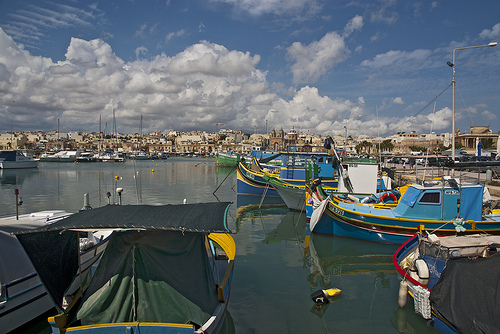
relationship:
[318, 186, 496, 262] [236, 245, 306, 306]
boat in water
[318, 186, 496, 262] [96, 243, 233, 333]
boat with tarp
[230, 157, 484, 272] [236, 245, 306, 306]
boats in water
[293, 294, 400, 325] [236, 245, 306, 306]
object in water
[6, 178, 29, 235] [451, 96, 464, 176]
light on a pole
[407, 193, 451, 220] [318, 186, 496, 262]
cabin of boat